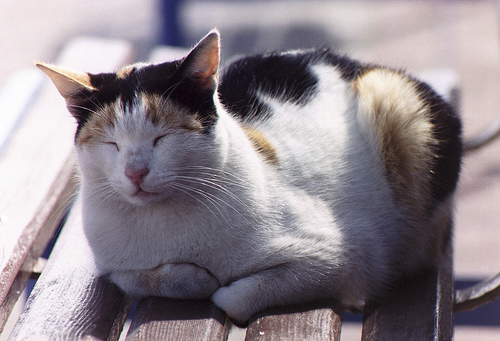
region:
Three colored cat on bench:
[37, 29, 465, 310]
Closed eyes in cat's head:
[99, 130, 179, 150]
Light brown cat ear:
[27, 60, 94, 95]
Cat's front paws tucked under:
[110, 264, 300, 311]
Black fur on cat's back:
[225, 50, 323, 107]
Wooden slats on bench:
[22, 304, 460, 337]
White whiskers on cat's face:
[175, 164, 253, 225]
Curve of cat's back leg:
[361, 60, 462, 251]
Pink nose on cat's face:
[122, 169, 148, 180]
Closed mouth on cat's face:
[127, 188, 157, 198]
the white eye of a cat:
[96, 135, 123, 159]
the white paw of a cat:
[103, 257, 224, 302]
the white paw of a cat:
[205, 262, 331, 326]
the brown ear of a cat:
[33, 59, 103, 102]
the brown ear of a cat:
[157, 23, 230, 85]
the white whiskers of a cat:
[42, 164, 280, 242]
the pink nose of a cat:
[116, 149, 156, 184]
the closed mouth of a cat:
[123, 182, 164, 204]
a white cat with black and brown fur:
[29, 37, 497, 323]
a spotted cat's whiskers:
[42, 159, 256, 237]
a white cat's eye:
[150, 124, 171, 150]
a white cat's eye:
[97, 136, 124, 154]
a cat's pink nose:
[119, 162, 150, 185]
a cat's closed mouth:
[125, 181, 162, 205]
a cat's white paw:
[148, 259, 220, 308]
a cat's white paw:
[208, 258, 326, 332]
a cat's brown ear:
[170, 21, 222, 100]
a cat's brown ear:
[33, 54, 104, 107]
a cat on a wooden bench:
[0, 34, 456, 339]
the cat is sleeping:
[31, 26, 413, 323]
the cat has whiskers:
[42, 156, 229, 253]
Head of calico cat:
[28, 28, 242, 208]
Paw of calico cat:
[204, 278, 271, 323]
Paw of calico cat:
[151, 264, 218, 302]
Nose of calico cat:
[116, 163, 156, 182]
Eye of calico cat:
[96, 131, 124, 156]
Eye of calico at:
[151, 125, 183, 150]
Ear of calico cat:
[36, 58, 96, 104]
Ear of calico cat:
[181, 25, 228, 86]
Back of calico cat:
[242, 58, 333, 111]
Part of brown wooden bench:
[129, 316, 192, 339]